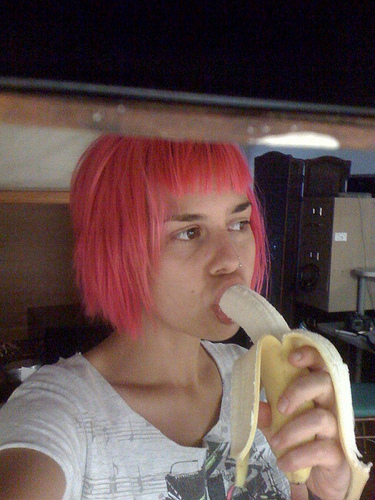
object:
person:
[0, 128, 353, 499]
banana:
[218, 282, 373, 499]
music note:
[101, 426, 112, 446]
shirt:
[0, 339, 294, 498]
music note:
[105, 468, 121, 497]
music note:
[134, 463, 144, 496]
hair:
[67, 130, 274, 346]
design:
[165, 439, 291, 499]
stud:
[237, 262, 244, 270]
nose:
[208, 218, 242, 278]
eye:
[223, 217, 252, 233]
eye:
[169, 222, 201, 243]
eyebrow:
[228, 200, 254, 214]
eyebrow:
[160, 210, 205, 222]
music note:
[124, 411, 134, 445]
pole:
[354, 276, 364, 318]